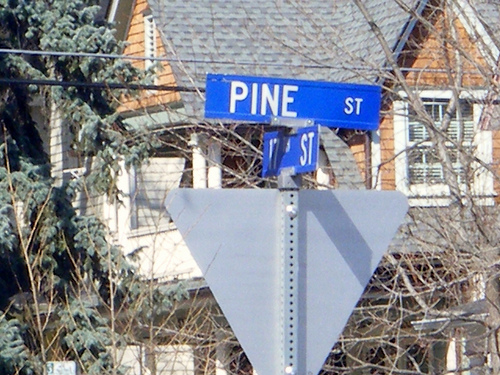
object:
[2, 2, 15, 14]
leaves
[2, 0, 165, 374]
tree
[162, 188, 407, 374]
sign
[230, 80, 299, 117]
pine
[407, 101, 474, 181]
mini blinds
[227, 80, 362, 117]
lettering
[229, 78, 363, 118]
text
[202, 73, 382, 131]
signs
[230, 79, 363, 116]
text print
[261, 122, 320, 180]
signs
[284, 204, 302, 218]
screw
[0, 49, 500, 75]
power lines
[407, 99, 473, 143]
window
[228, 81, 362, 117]
writing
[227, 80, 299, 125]
word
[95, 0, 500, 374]
tree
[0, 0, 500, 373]
house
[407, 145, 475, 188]
window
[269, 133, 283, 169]
number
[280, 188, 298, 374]
pole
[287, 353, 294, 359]
holes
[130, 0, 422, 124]
roof